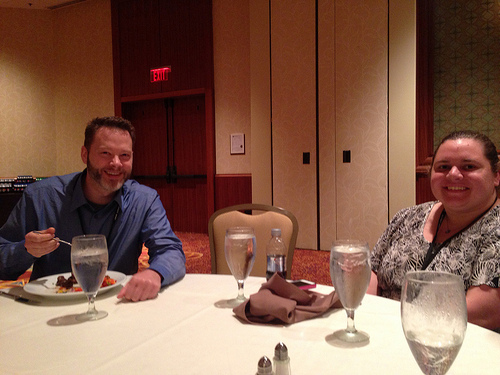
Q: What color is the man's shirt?
A: Dark blue.